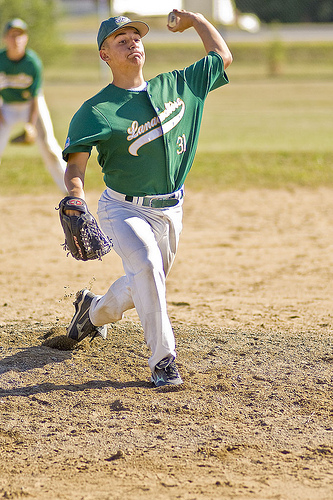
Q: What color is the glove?
A: Black.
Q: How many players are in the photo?
A: Two.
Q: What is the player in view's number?
A: Thirty-One.